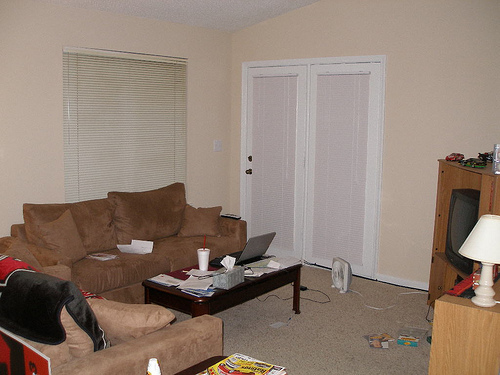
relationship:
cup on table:
[195, 247, 211, 270] [140, 259, 303, 318]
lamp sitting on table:
[458, 215, 499, 308] [427, 296, 498, 373]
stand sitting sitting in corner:
[426, 159, 500, 308] [375, 17, 484, 373]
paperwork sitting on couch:
[114, 236, 156, 258] [1, 175, 259, 301]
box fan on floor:
[331, 257, 353, 294] [291, 291, 389, 370]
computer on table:
[217, 233, 274, 264] [142, 252, 302, 332]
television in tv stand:
[445, 185, 478, 281] [422, 132, 496, 317]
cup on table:
[197, 248, 210, 271] [139, 252, 301, 317]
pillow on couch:
[178, 202, 222, 236] [1, 169, 247, 306]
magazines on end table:
[201, 353, 287, 373] [166, 350, 281, 373]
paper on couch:
[111, 238, 153, 257] [2, 183, 245, 309]